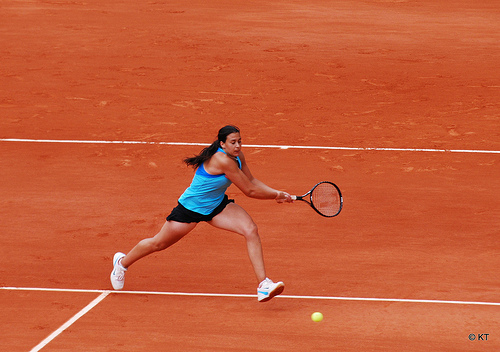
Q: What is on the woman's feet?
A: White and blue tennis shoes.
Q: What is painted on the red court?
A: White lines.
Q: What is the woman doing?
A: Playing tennis.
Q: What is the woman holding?
A: A tennis racket.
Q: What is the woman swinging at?
A: A tennis ball.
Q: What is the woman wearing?
A: A blue top and black shorts.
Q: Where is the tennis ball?
A: In the air and going toward the woman.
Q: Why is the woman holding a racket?
A: To hit the ball.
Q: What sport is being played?
A: Tennis.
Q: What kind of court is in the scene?
A: Clay.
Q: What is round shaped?
A: Tennis ball.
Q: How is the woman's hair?
A: In a ponytail.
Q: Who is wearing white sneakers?
A: The woman.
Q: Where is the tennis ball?
A: In the air.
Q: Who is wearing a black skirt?
A: Tennis player.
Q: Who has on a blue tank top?
A: Woman playing tennis.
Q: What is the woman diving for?
A: Tennis ball.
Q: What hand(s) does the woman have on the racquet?
A: Both.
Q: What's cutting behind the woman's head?
A: Boundary line.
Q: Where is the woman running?
A: On a tennis court.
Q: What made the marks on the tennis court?
A: Feet.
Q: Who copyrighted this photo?
A: KT.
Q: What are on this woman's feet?
A: Tennis shoes.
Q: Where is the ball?
A: In the air.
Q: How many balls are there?
A: One.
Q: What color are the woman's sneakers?
A: White.